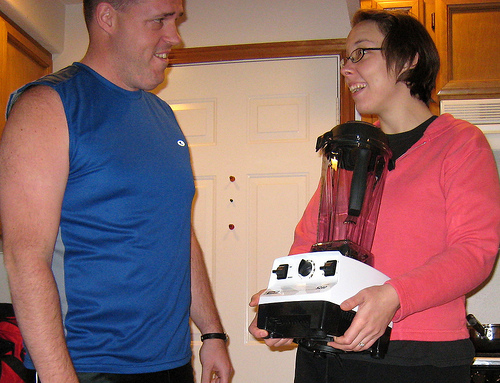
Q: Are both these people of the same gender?
A: No, they are both male and female.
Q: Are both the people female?
A: No, they are both male and female.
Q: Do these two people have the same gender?
A: No, they are both male and female.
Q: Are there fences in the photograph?
A: No, there are no fences.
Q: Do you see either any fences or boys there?
A: No, there are no fences or boys.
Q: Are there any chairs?
A: No, there are no chairs.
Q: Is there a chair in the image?
A: No, there are no chairs.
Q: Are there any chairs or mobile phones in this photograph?
A: No, there are no chairs or mobile phones.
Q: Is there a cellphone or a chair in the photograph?
A: No, there are no chairs or cell phones.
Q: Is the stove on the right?
A: Yes, the stove is on the right of the image.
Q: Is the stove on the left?
A: No, the stove is on the right of the image.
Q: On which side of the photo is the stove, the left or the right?
A: The stove is on the right of the image.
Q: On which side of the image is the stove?
A: The stove is on the right of the image.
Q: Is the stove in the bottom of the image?
A: Yes, the stove is in the bottom of the image.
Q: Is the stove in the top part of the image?
A: No, the stove is in the bottom of the image.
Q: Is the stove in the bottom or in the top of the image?
A: The stove is in the bottom of the image.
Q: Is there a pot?
A: Yes, there is a pot.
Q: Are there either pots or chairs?
A: Yes, there is a pot.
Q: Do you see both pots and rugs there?
A: No, there is a pot but no rugs.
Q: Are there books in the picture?
A: No, there are no books.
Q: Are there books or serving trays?
A: No, there are no books or serving trays.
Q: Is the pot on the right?
A: Yes, the pot is on the right of the image.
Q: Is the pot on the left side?
A: No, the pot is on the right of the image.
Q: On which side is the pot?
A: The pot is on the right of the image.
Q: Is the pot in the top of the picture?
A: No, the pot is in the bottom of the image.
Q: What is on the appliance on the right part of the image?
A: The pot is on the stove.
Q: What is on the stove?
A: The pot is on the stove.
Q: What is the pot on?
A: The pot is on the stove.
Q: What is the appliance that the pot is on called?
A: The appliance is a stove.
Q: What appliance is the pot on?
A: The pot is on the stove.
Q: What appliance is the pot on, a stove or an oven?
A: The pot is on a stove.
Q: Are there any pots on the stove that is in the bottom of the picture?
A: Yes, there is a pot on the stove.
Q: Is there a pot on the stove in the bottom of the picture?
A: Yes, there is a pot on the stove.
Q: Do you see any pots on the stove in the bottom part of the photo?
A: Yes, there is a pot on the stove.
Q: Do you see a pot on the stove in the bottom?
A: Yes, there is a pot on the stove.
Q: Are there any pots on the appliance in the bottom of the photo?
A: Yes, there is a pot on the stove.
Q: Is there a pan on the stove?
A: No, there is a pot on the stove.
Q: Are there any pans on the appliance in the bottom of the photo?
A: No, there is a pot on the stove.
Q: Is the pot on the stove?
A: Yes, the pot is on the stove.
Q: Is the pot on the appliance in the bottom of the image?
A: Yes, the pot is on the stove.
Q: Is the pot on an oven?
A: No, the pot is on the stove.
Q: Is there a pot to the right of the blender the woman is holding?
A: Yes, there is a pot to the right of the blender.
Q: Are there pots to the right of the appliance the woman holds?
A: Yes, there is a pot to the right of the blender.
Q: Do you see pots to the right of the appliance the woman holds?
A: Yes, there is a pot to the right of the blender.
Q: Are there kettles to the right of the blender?
A: No, there is a pot to the right of the blender.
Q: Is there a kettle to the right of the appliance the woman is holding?
A: No, there is a pot to the right of the blender.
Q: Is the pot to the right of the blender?
A: Yes, the pot is to the right of the blender.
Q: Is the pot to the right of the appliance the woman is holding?
A: Yes, the pot is to the right of the blender.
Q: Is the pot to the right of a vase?
A: No, the pot is to the right of the blender.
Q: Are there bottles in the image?
A: No, there are no bottles.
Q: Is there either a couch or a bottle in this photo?
A: No, there are no bottles or couches.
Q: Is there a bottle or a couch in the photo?
A: No, there are no bottles or couches.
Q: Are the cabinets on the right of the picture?
A: Yes, the cabinets are on the right of the image.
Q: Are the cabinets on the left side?
A: No, the cabinets are on the right of the image.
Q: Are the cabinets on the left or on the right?
A: The cabinets are on the right of the image.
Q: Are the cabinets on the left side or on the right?
A: The cabinets are on the right of the image.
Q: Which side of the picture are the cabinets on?
A: The cabinets are on the right of the image.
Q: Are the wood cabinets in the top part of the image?
A: Yes, the cabinets are in the top of the image.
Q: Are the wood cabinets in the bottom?
A: No, the cabinets are in the top of the image.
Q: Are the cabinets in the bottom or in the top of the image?
A: The cabinets are in the top of the image.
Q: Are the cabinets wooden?
A: Yes, the cabinets are wooden.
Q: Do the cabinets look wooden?
A: Yes, the cabinets are wooden.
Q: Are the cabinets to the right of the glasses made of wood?
A: Yes, the cabinets are made of wood.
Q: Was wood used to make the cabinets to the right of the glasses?
A: Yes, the cabinets are made of wood.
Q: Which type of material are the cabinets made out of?
A: The cabinets are made of wood.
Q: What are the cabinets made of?
A: The cabinets are made of wood.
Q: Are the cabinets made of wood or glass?
A: The cabinets are made of wood.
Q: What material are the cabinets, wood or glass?
A: The cabinets are made of wood.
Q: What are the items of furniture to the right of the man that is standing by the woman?
A: The pieces of furniture are cabinets.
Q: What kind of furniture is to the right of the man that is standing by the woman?
A: The pieces of furniture are cabinets.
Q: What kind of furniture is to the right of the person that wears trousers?
A: The pieces of furniture are cabinets.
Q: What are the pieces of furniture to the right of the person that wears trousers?
A: The pieces of furniture are cabinets.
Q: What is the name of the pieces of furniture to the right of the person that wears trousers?
A: The pieces of furniture are cabinets.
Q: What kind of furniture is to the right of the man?
A: The pieces of furniture are cabinets.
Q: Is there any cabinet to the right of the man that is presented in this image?
A: Yes, there are cabinets to the right of the man.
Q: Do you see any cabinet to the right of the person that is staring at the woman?
A: Yes, there are cabinets to the right of the man.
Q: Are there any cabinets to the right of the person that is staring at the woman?
A: Yes, there are cabinets to the right of the man.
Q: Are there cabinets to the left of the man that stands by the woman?
A: No, the cabinets are to the right of the man.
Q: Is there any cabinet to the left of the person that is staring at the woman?
A: No, the cabinets are to the right of the man.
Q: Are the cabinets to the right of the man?
A: Yes, the cabinets are to the right of the man.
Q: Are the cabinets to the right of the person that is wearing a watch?
A: Yes, the cabinets are to the right of the man.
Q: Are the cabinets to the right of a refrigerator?
A: No, the cabinets are to the right of the man.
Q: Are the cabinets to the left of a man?
A: No, the cabinets are to the right of a man.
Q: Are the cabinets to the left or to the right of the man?
A: The cabinets are to the right of the man.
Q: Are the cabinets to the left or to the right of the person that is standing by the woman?
A: The cabinets are to the right of the man.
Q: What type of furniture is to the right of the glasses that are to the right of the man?
A: The pieces of furniture are cabinets.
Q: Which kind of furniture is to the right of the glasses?
A: The pieces of furniture are cabinets.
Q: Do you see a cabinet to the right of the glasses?
A: Yes, there are cabinets to the right of the glasses.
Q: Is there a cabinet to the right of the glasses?
A: Yes, there are cabinets to the right of the glasses.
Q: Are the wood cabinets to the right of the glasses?
A: Yes, the cabinets are to the right of the glasses.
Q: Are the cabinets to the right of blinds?
A: No, the cabinets are to the right of the glasses.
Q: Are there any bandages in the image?
A: No, there are no bandages.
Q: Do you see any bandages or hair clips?
A: No, there are no bandages or hair clips.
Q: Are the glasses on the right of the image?
A: Yes, the glasses are on the right of the image.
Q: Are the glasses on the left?
A: No, the glasses are on the right of the image.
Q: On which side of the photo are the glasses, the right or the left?
A: The glasses are on the right of the image.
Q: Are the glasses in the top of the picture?
A: Yes, the glasses are in the top of the image.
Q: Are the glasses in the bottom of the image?
A: No, the glasses are in the top of the image.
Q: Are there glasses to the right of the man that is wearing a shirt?
A: Yes, there are glasses to the right of the man.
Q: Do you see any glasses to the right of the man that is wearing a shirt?
A: Yes, there are glasses to the right of the man.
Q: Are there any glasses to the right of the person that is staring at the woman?
A: Yes, there are glasses to the right of the man.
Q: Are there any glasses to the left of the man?
A: No, the glasses are to the right of the man.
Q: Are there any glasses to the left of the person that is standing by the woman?
A: No, the glasses are to the right of the man.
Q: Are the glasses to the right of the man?
A: Yes, the glasses are to the right of the man.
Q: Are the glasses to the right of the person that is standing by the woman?
A: Yes, the glasses are to the right of the man.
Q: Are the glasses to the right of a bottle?
A: No, the glasses are to the right of the man.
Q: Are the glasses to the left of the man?
A: No, the glasses are to the right of the man.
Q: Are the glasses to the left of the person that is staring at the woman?
A: No, the glasses are to the right of the man.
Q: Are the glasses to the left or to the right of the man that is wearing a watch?
A: The glasses are to the right of the man.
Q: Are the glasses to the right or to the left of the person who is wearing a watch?
A: The glasses are to the right of the man.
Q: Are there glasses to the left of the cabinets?
A: Yes, there are glasses to the left of the cabinets.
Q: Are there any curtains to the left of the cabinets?
A: No, there are glasses to the left of the cabinets.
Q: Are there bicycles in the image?
A: No, there are no bicycles.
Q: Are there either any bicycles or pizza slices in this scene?
A: No, there are no bicycles or pizza slices.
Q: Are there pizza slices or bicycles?
A: No, there are no bicycles or pizza slices.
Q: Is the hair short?
A: Yes, the hair is short.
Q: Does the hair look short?
A: Yes, the hair is short.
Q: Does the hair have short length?
A: Yes, the hair is short.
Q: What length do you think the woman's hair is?
A: The hair is short.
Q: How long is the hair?
A: The hair is short.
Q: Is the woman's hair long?
A: No, the hair is short.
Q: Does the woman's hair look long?
A: No, the hair is short.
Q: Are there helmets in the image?
A: No, there are no helmets.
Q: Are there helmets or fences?
A: No, there are no helmets or fences.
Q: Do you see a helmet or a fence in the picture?
A: No, there are no helmets or fences.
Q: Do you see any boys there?
A: No, there are no boys.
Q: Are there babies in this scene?
A: No, there are no babies.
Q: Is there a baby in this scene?
A: No, there are no babies.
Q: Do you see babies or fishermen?
A: No, there are no babies or fishermen.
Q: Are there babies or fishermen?
A: No, there are no babies or fishermen.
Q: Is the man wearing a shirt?
A: Yes, the man is wearing a shirt.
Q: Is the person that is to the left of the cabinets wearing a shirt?
A: Yes, the man is wearing a shirt.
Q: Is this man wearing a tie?
A: No, the man is wearing a shirt.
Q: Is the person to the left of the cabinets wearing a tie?
A: No, the man is wearing a shirt.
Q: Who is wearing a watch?
A: The man is wearing a watch.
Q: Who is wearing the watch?
A: The man is wearing a watch.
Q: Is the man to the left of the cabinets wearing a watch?
A: Yes, the man is wearing a watch.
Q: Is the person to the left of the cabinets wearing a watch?
A: Yes, the man is wearing a watch.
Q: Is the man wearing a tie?
A: No, the man is wearing a watch.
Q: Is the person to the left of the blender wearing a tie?
A: No, the man is wearing a watch.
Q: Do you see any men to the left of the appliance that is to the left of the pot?
A: Yes, there is a man to the left of the blender.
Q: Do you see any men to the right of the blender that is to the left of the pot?
A: No, the man is to the left of the blender.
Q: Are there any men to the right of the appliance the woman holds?
A: No, the man is to the left of the blender.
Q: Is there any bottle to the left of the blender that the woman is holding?
A: No, there is a man to the left of the blender.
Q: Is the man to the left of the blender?
A: Yes, the man is to the left of the blender.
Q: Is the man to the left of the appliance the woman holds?
A: Yes, the man is to the left of the blender.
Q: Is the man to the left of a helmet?
A: No, the man is to the left of the blender.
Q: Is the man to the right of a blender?
A: No, the man is to the left of a blender.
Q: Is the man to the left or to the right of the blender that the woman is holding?
A: The man is to the left of the blender.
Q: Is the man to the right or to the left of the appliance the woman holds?
A: The man is to the left of the blender.